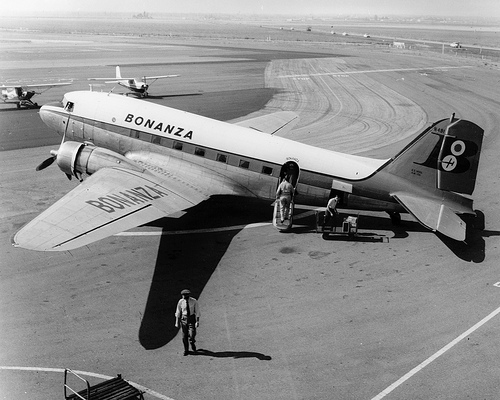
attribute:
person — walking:
[162, 273, 214, 361]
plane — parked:
[60, 88, 480, 260]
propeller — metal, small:
[33, 128, 78, 187]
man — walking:
[142, 276, 231, 368]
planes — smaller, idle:
[9, 58, 159, 116]